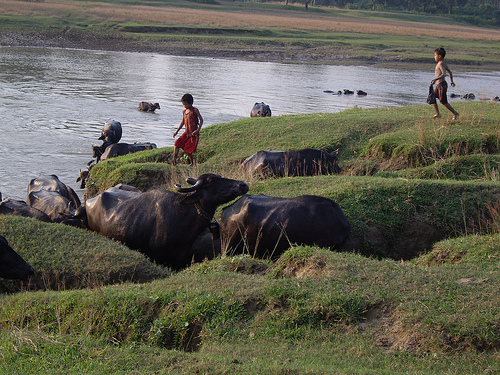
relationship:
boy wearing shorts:
[422, 45, 464, 125] [429, 77, 446, 104]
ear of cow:
[180, 192, 202, 205] [84, 173, 352, 273]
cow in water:
[139, 101, 160, 112] [1, 42, 498, 199]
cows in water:
[324, 89, 367, 96] [16, 33, 463, 138]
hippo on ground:
[223, 196, 353, 253] [38, 250, 442, 370]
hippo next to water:
[0, 170, 90, 222] [1, 42, 498, 199]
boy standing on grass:
[174, 92, 203, 165] [342, 114, 427, 154]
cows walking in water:
[324, 89, 367, 96] [1, 42, 498, 199]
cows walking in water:
[448, 91, 498, 101] [1, 42, 498, 199]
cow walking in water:
[248, 100, 274, 117] [1, 42, 498, 199]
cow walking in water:
[138, 101, 162, 112] [1, 42, 498, 199]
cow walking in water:
[84, 173, 352, 273] [1, 42, 498, 199]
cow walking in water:
[236, 150, 341, 180] [1, 42, 498, 199]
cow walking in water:
[356, 89, 368, 96] [1, 42, 498, 199]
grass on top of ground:
[0, 100, 500, 375] [194, 256, 498, 371]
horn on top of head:
[174, 177, 204, 192] [177, 171, 308, 195]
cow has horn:
[129, 156, 356, 208] [174, 177, 204, 192]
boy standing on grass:
[168, 93, 203, 165] [250, 113, 448, 190]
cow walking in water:
[242, 147, 341, 180] [8, 49, 138, 119]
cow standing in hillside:
[84, 173, 352, 273] [73, 249, 476, 369]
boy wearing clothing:
[168, 93, 203, 165] [173, 117, 199, 153]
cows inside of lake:
[320, 88, 369, 97] [13, 38, 431, 118]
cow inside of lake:
[250, 102, 271, 117] [13, 38, 431, 118]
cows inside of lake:
[450, 93, 500, 101] [13, 38, 431, 118]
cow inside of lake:
[139, 101, 160, 112] [13, 38, 431, 118]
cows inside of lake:
[71, 165, 87, 191] [13, 38, 431, 118]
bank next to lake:
[3, 33, 498, 71] [1, 46, 498, 193]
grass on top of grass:
[3, 102, 498, 374] [0, 100, 500, 375]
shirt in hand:
[425, 79, 435, 105] [430, 81, 434, 84]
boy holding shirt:
[427, 48, 460, 120] [425, 79, 435, 105]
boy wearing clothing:
[168, 93, 203, 165] [174, 105, 199, 154]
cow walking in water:
[139, 101, 160, 112] [12, 55, 175, 140]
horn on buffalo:
[174, 181, 205, 194] [208, 189, 384, 280]